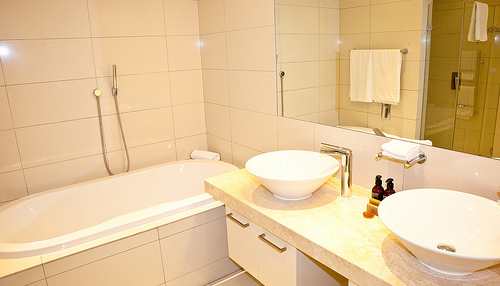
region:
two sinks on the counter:
[262, 150, 498, 279]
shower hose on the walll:
[27, 39, 143, 173]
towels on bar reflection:
[329, 42, 426, 110]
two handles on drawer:
[221, 210, 319, 258]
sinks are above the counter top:
[250, 155, 491, 284]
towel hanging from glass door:
[471, 6, 487, 43]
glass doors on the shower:
[428, 32, 493, 178]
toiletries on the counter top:
[346, 168, 412, 224]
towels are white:
[343, 43, 423, 117]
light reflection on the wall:
[0, 43, 25, 74]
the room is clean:
[55, 65, 197, 179]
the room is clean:
[79, 92, 314, 280]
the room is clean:
[172, 152, 340, 260]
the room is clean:
[216, 104, 370, 258]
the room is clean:
[280, 214, 328, 249]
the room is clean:
[280, 172, 412, 246]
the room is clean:
[285, 97, 460, 261]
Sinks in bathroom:
[235, 125, 499, 252]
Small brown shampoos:
[362, 166, 403, 196]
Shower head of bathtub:
[72, 49, 157, 181]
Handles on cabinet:
[220, 200, 292, 266]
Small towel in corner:
[189, 139, 230, 174]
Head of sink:
[323, 137, 358, 198]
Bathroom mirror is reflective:
[278, 17, 495, 113]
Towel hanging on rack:
[338, 42, 415, 111]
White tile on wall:
[1, 41, 99, 78]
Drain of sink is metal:
[436, 237, 454, 258]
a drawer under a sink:
[213, 208, 324, 282]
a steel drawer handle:
[251, 229, 291, 261]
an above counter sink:
[248, 131, 355, 207]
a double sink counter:
[233, 126, 475, 284]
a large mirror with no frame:
[260, 17, 499, 137]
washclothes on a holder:
[371, 123, 432, 173]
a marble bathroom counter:
[205, 174, 391, 283]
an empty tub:
[23, 181, 230, 247]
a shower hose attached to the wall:
[76, 57, 168, 175]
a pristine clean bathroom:
[6, 10, 477, 256]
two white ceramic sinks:
[245, 138, 498, 269]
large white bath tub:
[7, 185, 222, 236]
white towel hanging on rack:
[340, 43, 406, 108]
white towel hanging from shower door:
[469, 2, 490, 42]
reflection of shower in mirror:
[264, 5, 494, 142]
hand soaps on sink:
[362, 172, 395, 214]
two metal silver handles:
[220, 210, 297, 263]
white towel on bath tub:
[184, 140, 221, 164]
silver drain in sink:
[434, 235, 465, 266]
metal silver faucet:
[317, 134, 362, 198]